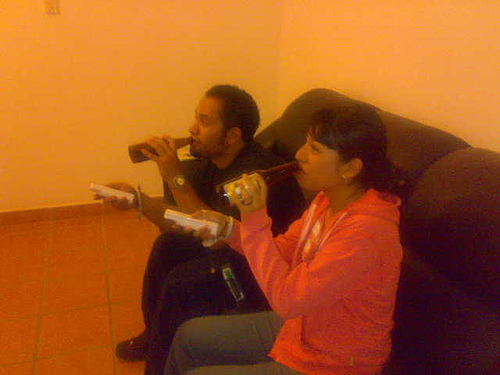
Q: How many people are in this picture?
A: Two.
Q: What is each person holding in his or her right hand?
A: A bottle.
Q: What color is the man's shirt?
A: Black.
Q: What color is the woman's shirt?
A: Orange.